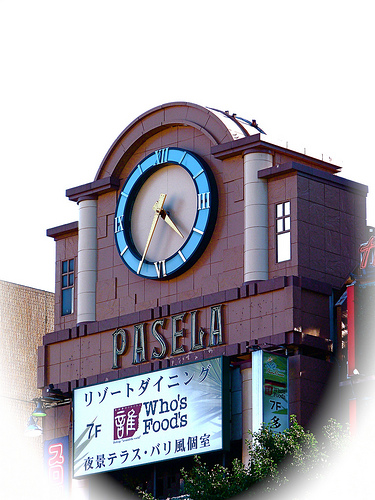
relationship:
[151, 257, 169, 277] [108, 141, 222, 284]
number on clock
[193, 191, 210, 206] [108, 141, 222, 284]
number on clock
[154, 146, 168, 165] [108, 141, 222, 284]
number on clock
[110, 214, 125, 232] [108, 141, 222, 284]
number on clock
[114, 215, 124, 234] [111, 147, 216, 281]
number on clock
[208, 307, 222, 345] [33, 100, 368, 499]
letter on building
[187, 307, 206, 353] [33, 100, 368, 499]
letter on building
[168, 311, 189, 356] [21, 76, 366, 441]
letter on building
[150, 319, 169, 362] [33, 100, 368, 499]
letter on building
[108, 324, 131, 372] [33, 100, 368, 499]
letter on building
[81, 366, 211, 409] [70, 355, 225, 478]
chinese writing on sign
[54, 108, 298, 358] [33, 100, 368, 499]
wall on building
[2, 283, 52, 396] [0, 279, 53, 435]
wall on building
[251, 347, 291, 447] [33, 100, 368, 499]
7f sign on building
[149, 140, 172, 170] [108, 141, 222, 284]
number on clock